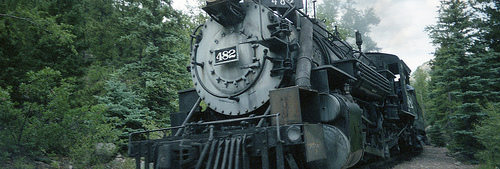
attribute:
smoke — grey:
[305, 0, 420, 59]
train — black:
[152, 2, 431, 167]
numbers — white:
[211, 40, 238, 67]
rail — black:
[122, 109, 295, 141]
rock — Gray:
[85, 141, 122, 160]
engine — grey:
[318, 90, 365, 167]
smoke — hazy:
[307, 1, 439, 65]